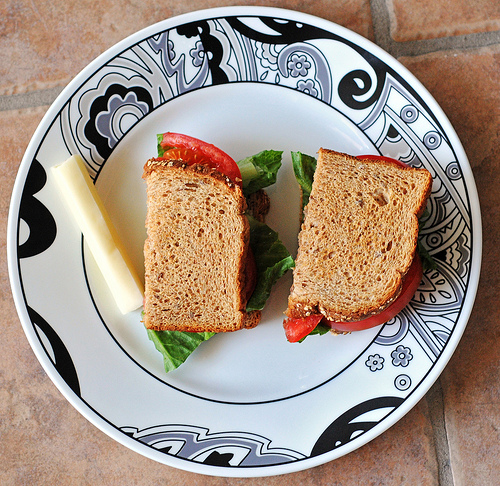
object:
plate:
[5, 4, 487, 481]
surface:
[0, 0, 498, 485]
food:
[50, 131, 433, 373]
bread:
[141, 156, 265, 335]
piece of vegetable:
[290, 149, 317, 222]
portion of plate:
[77, 78, 387, 407]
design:
[92, 16, 258, 87]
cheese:
[50, 151, 146, 318]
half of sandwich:
[139, 130, 295, 374]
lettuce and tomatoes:
[159, 130, 243, 192]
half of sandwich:
[281, 145, 435, 344]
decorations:
[16, 156, 59, 260]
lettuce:
[234, 147, 296, 313]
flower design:
[286, 53, 312, 79]